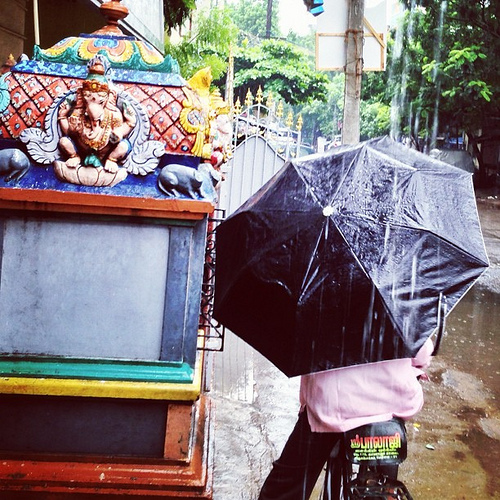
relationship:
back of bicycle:
[346, 417, 412, 470] [312, 426, 407, 496]